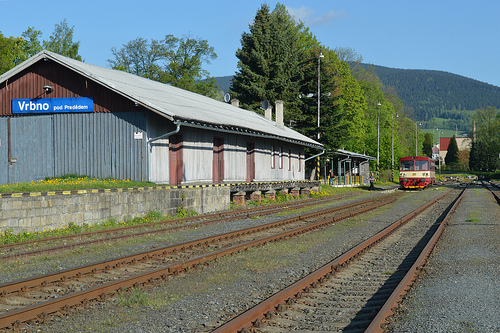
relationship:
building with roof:
[25, 32, 357, 269] [79, 48, 357, 174]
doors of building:
[167, 130, 280, 195] [25, 42, 360, 228]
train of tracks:
[399, 156, 437, 189] [128, 179, 460, 325]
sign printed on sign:
[11, 96, 93, 114] [10, 96, 93, 114]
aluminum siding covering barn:
[1, 114, 151, 188] [0, 46, 327, 186]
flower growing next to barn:
[46, 177, 48, 179] [0, 46, 327, 186]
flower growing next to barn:
[67, 180, 70, 182] [0, 46, 327, 186]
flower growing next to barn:
[95, 177, 98, 179] [0, 46, 327, 186]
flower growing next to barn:
[106, 180, 108, 181] [0, 46, 327, 186]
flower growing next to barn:
[30, 180, 34, 183] [0, 46, 327, 186]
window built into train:
[399, 158, 415, 172] [397, 152, 437, 189]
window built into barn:
[270, 144, 276, 168] [0, 46, 327, 186]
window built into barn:
[278, 148, 283, 170] [0, 46, 327, 186]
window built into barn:
[287, 145, 292, 170] [0, 46, 327, 186]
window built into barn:
[297, 151, 302, 172] [0, 46, 327, 186]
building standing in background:
[443, 119, 477, 169] [194, 60, 482, 181]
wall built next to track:
[1, 179, 231, 236] [1, 190, 361, 262]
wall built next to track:
[1, 179, 231, 236] [1, 188, 405, 330]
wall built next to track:
[1, 179, 231, 236] [206, 180, 469, 331]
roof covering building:
[438, 135, 463, 149] [437, 134, 467, 168]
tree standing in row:
[227, 2, 307, 128] [225, 1, 435, 170]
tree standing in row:
[291, 50, 351, 168] [225, 1, 435, 170]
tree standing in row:
[321, 44, 366, 149] [225, 1, 435, 170]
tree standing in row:
[358, 78, 404, 172] [225, 1, 435, 170]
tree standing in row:
[399, 113, 420, 156] [225, 1, 435, 170]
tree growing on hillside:
[423, 110, 428, 120] [193, 59, 483, 139]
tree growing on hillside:
[457, 100, 461, 109] [193, 59, 483, 139]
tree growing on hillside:
[447, 88, 451, 95] [193, 59, 483, 139]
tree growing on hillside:
[427, 75, 430, 81] [193, 59, 483, 139]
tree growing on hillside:
[394, 78, 399, 84] [193, 59, 483, 139]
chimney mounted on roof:
[274, 99, 287, 131] [6, 43, 327, 150]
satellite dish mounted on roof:
[259, 97, 271, 110] [6, 43, 327, 150]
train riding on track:
[399, 156, 437, 189] [1, 188, 405, 330]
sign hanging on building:
[10, 96, 93, 114] [0, 46, 326, 186]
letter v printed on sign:
[16, 99, 26, 112] [10, 96, 93, 114]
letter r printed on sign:
[23, 102, 30, 111] [10, 94, 95, 114]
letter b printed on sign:
[29, 99, 37, 111] [10, 94, 95, 114]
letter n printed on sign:
[34, 100, 43, 111] [10, 94, 95, 114]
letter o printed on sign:
[41, 100, 48, 110] [11, 95, 94, 115]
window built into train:
[399, 158, 415, 172] [399, 156, 437, 189]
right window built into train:
[414, 158, 428, 171] [399, 156, 437, 189]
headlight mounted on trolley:
[398, 171, 402, 176] [397, 155, 437, 190]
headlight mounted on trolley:
[402, 171, 406, 176] [397, 155, 437, 190]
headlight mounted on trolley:
[421, 170, 425, 175] [397, 155, 437, 190]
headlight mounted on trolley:
[424, 171, 428, 176] [397, 155, 437, 190]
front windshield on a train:
[399, 159, 433, 172] [395, 153, 438, 191]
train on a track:
[393, 157, 442, 191] [4, 181, 429, 319]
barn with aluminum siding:
[0, 46, 327, 186] [1, 114, 151, 188]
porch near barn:
[230, 179, 337, 219] [4, 48, 333, 208]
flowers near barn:
[28, 170, 148, 191] [6, 48, 313, 198]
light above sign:
[41, 75, 59, 96] [8, 88, 95, 118]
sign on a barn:
[11, 96, 93, 114] [4, 48, 333, 208]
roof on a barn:
[6, 43, 327, 150] [0, 46, 327, 186]